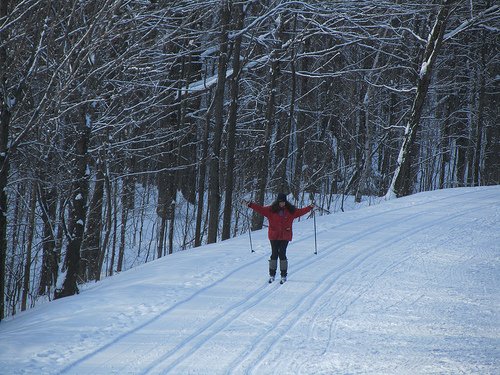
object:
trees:
[0, 9, 92, 142]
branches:
[124, 48, 156, 88]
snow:
[187, 81, 207, 91]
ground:
[58, 281, 114, 348]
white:
[196, 352, 222, 366]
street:
[140, 276, 337, 366]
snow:
[167, 254, 230, 284]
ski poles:
[245, 206, 317, 255]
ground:
[277, 188, 496, 375]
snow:
[455, 185, 500, 373]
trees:
[220, 0, 311, 180]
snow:
[0, 25, 66, 160]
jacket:
[246, 202, 316, 241]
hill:
[0, 186, 184, 375]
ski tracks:
[50, 186, 500, 375]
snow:
[103, 238, 176, 279]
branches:
[54, 43, 117, 269]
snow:
[0, 309, 40, 372]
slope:
[37, 256, 244, 373]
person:
[241, 193, 316, 284]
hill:
[341, 190, 500, 375]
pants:
[268, 240, 289, 277]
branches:
[0, 46, 36, 298]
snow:
[387, 260, 426, 375]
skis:
[268, 259, 289, 284]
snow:
[316, 203, 333, 262]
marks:
[158, 296, 292, 373]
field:
[0, 208, 500, 375]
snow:
[180, 307, 236, 375]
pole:
[245, 207, 255, 253]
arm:
[294, 203, 316, 218]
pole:
[312, 210, 317, 255]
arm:
[244, 201, 272, 216]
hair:
[269, 199, 296, 214]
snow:
[300, 317, 361, 375]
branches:
[184, 53, 209, 101]